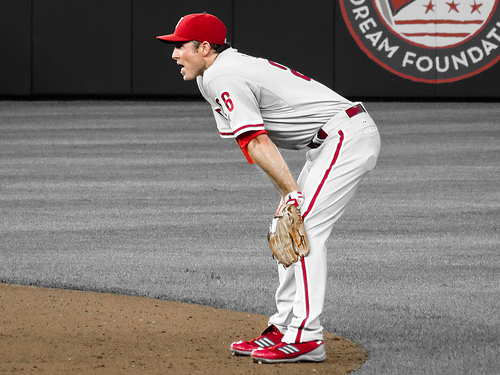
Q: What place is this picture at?
A: It is at the field.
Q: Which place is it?
A: It is a field.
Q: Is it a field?
A: Yes, it is a field.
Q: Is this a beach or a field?
A: It is a field.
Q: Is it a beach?
A: No, it is a field.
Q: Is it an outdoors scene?
A: Yes, it is outdoors.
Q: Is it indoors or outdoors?
A: It is outdoors.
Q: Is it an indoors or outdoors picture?
A: It is outdoors.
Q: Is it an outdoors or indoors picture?
A: It is outdoors.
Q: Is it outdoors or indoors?
A: It is outdoors.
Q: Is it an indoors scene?
A: No, it is outdoors.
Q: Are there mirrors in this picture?
A: No, there are no mirrors.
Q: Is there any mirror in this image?
A: No, there are no mirrors.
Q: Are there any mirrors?
A: No, there are no mirrors.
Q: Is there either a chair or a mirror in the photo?
A: No, there are no mirrors or chairs.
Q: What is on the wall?
A: The logo is on the wall.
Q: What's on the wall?
A: The logo is on the wall.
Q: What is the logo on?
A: The logo is on the wall.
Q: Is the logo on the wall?
A: Yes, the logo is on the wall.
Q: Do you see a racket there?
A: No, there are no rackets.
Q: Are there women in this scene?
A: No, there are no women.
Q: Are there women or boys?
A: No, there are no women or boys.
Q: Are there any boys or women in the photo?
A: No, there are no women or boys.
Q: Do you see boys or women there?
A: No, there are no women or boys.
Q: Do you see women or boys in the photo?
A: No, there are no women or boys.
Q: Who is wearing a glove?
A: The man is wearing a glove.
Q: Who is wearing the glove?
A: The man is wearing a glove.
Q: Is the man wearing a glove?
A: Yes, the man is wearing a glove.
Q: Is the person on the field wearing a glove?
A: Yes, the man is wearing a glove.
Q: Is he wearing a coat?
A: No, the man is wearing a glove.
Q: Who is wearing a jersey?
A: The man is wearing a jersey.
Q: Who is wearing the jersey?
A: The man is wearing a jersey.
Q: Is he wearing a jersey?
A: Yes, the man is wearing a jersey.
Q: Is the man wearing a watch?
A: No, the man is wearing a jersey.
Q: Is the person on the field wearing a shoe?
A: Yes, the man is wearing a shoe.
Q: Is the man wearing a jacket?
A: No, the man is wearing a shoe.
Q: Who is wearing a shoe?
A: The man is wearing a shoe.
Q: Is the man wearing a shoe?
A: Yes, the man is wearing a shoe.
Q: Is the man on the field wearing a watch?
A: No, the man is wearing a shoe.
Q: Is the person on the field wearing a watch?
A: No, the man is wearing a shoe.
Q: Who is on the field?
A: The man is on the field.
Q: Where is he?
A: The man is on the field.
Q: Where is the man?
A: The man is on the field.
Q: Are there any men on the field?
A: Yes, there is a man on the field.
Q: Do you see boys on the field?
A: No, there is a man on the field.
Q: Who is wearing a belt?
A: The man is wearing a belt.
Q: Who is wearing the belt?
A: The man is wearing a belt.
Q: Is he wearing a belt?
A: Yes, the man is wearing a belt.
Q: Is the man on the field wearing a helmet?
A: No, the man is wearing a belt.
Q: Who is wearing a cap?
A: The man is wearing a cap.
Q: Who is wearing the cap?
A: The man is wearing a cap.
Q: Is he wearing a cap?
A: Yes, the man is wearing a cap.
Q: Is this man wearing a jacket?
A: No, the man is wearing a cap.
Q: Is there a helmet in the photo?
A: No, there are no helmets.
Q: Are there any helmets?
A: No, there are no helmets.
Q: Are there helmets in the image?
A: No, there are no helmets.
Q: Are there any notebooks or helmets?
A: No, there are no helmets or notebooks.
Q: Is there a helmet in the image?
A: No, there are no helmets.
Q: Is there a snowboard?
A: No, there are no snowboards.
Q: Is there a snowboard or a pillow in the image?
A: No, there are no snowboards or pillows.